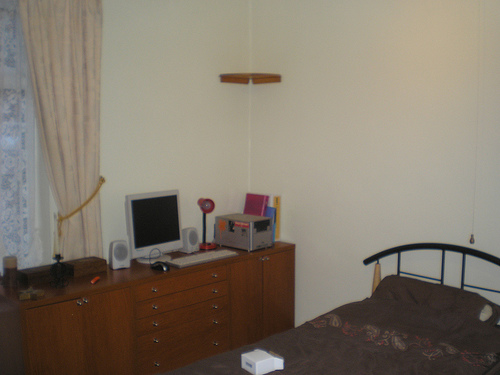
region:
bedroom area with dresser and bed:
[4, 6, 478, 371]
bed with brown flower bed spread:
[330, 242, 497, 371]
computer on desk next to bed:
[108, 188, 238, 269]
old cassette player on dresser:
[213, 210, 274, 251]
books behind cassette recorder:
[240, 188, 282, 245]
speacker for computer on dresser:
[108, 239, 133, 270]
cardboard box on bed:
[240, 350, 287, 371]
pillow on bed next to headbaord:
[376, 273, 498, 330]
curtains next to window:
[34, 69, 102, 259]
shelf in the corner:
[171, 61, 296, 111]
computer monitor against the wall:
[122, 183, 194, 265]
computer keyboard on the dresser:
[151, 243, 241, 275]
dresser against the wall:
[63, 216, 335, 370]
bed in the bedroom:
[238, 193, 490, 372]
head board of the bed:
[332, 235, 499, 291]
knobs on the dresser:
[131, 267, 234, 361]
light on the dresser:
[184, 188, 230, 264]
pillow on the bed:
[354, 280, 489, 330]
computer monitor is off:
[126, 189, 187, 262]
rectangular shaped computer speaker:
[104, 236, 134, 271]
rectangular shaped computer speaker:
[185, 222, 200, 253]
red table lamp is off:
[195, 193, 220, 248]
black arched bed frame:
[360, 235, 496, 291]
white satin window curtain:
[33, 18, 114, 259]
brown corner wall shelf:
[222, 62, 284, 85]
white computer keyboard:
[171, 245, 242, 267]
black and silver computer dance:
[146, 255, 166, 275]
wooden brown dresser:
[6, 260, 267, 352]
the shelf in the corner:
[217, 69, 282, 86]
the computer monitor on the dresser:
[126, 190, 181, 264]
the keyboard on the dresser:
[168, 245, 237, 267]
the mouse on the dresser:
[150, 259, 169, 272]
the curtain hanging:
[18, 0, 105, 265]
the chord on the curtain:
[53, 175, 105, 236]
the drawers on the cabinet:
[131, 263, 233, 374]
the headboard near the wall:
[361, 242, 498, 308]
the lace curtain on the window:
[1, 0, 56, 267]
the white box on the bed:
[239, 346, 284, 373]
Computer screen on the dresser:
[96, 162, 196, 278]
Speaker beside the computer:
[97, 235, 137, 282]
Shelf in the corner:
[210, 53, 290, 115]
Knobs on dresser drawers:
[129, 287, 247, 365]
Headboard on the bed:
[367, 202, 493, 323]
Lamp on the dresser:
[189, 186, 224, 250]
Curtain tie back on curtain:
[44, 140, 153, 282]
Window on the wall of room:
[2, 108, 47, 250]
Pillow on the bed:
[362, 255, 484, 372]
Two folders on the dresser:
[227, 176, 297, 239]